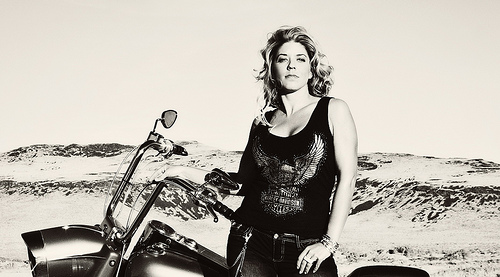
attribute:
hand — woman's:
[291, 239, 332, 273]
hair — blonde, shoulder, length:
[240, 19, 354, 137]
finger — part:
[310, 257, 320, 274]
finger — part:
[301, 260, 312, 274]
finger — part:
[296, 258, 308, 274]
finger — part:
[292, 247, 307, 267]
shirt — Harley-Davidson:
[237, 98, 364, 245]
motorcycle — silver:
[18, 86, 433, 275]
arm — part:
[317, 164, 371, 231]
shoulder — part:
[319, 95, 357, 127]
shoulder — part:
[247, 110, 274, 132]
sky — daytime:
[7, 9, 244, 104]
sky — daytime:
[352, 8, 499, 132]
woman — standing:
[78, 45, 494, 230]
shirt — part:
[237, 105, 334, 236]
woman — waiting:
[219, 25, 380, 275]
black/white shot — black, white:
[1, 0, 496, 275]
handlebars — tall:
[102, 109, 237, 240]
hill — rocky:
[9, 142, 496, 227]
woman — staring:
[219, 22, 361, 208]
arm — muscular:
[299, 95, 370, 273]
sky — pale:
[4, 3, 497, 177]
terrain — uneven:
[2, 132, 498, 274]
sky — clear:
[399, 27, 460, 78]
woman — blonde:
[204, 24, 359, 274]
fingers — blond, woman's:
[294, 245, 324, 275]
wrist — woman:
[318, 231, 340, 254]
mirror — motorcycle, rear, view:
[159, 109, 177, 129]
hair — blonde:
[260, 17, 332, 94]